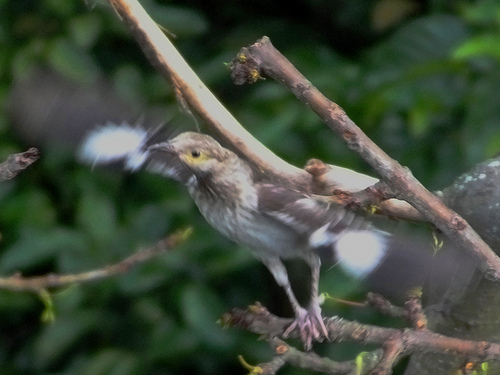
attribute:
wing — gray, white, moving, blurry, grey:
[72, 112, 208, 208]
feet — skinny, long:
[284, 309, 329, 345]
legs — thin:
[270, 253, 327, 314]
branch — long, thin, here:
[235, 291, 500, 374]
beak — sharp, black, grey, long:
[148, 138, 171, 154]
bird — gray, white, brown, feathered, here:
[90, 112, 396, 336]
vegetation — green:
[3, 5, 498, 375]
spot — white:
[80, 113, 149, 170]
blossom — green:
[234, 346, 266, 375]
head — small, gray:
[145, 126, 220, 179]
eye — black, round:
[190, 150, 203, 161]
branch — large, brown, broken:
[236, 32, 500, 278]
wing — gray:
[254, 181, 395, 267]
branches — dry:
[113, 6, 500, 374]